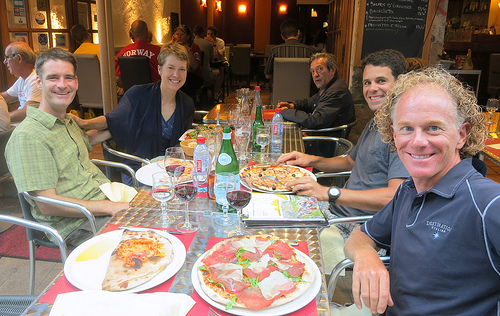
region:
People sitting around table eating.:
[18, 20, 473, 301]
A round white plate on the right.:
[181, 222, 321, 314]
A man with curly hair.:
[373, 62, 499, 204]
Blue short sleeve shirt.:
[348, 150, 498, 310]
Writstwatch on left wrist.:
[321, 180, 352, 210]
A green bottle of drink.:
[209, 122, 247, 209]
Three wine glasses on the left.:
[149, 144, 203, 228]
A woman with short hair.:
[98, 36, 195, 153]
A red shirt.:
[108, 33, 159, 80]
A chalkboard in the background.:
[359, 2, 436, 54]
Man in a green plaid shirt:
[4, 45, 146, 250]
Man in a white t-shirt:
[4, 41, 61, 133]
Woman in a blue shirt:
[103, 37, 213, 167]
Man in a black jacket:
[287, 49, 362, 139]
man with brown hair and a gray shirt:
[346, 56, 396, 213]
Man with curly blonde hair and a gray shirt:
[353, 67, 497, 279]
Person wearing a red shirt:
[115, 28, 167, 83]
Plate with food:
[197, 226, 331, 315]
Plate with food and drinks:
[196, 83, 349, 303]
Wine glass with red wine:
[207, 166, 277, 261]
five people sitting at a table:
[4, 37, 499, 311]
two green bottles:
[205, 93, 272, 217]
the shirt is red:
[110, 12, 169, 101]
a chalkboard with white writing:
[360, 0, 437, 67]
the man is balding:
[0, 32, 50, 149]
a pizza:
[189, 222, 326, 314]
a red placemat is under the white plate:
[185, 226, 326, 313]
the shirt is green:
[3, 92, 135, 257]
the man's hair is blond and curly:
[369, 56, 492, 172]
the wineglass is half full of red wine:
[223, 162, 258, 244]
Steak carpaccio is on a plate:
[201, 235, 318, 313]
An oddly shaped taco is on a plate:
[106, 223, 179, 299]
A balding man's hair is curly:
[373, 61, 486, 176]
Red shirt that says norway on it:
[104, 43, 174, 68]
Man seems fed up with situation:
[278, 44, 358, 139]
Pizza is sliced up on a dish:
[245, 155, 316, 205]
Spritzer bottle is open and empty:
[204, 122, 247, 222]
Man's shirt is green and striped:
[13, 107, 128, 238]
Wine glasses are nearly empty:
[142, 123, 258, 242]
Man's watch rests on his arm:
[318, 172, 348, 213]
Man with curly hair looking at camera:
[391, 63, 488, 176]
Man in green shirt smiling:
[26, 38, 84, 165]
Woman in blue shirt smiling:
[138, 40, 195, 131]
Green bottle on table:
[211, 111, 241, 217]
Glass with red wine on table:
[218, 164, 266, 239]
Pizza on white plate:
[189, 225, 326, 315]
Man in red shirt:
[111, 7, 160, 82]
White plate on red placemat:
[101, 217, 194, 305]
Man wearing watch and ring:
[286, 167, 368, 212]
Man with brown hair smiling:
[351, 45, 403, 113]